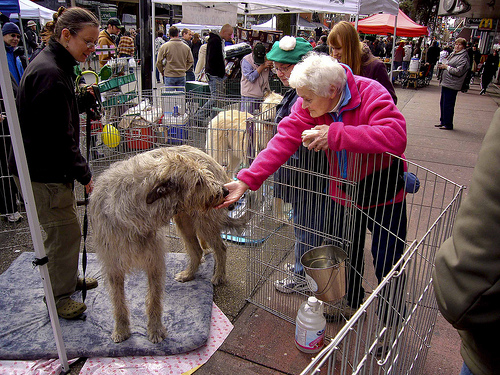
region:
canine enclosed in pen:
[8, 61, 442, 371]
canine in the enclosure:
[82, 138, 252, 337]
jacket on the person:
[17, 45, 97, 174]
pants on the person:
[8, 177, 85, 296]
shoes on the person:
[51, 270, 101, 322]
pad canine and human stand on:
[2, 243, 224, 350]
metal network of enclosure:
[356, 173, 422, 244]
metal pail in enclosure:
[303, 237, 357, 295]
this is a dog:
[92, 144, 214, 335]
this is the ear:
[148, 175, 180, 201]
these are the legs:
[104, 266, 170, 353]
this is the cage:
[353, 165, 443, 260]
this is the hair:
[299, 53, 341, 85]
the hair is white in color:
[297, 57, 342, 84]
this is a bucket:
[297, 246, 351, 289]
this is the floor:
[420, 133, 476, 160]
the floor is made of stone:
[423, 135, 473, 160]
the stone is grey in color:
[416, 133, 466, 159]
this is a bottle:
[292, 289, 329, 352]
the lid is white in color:
[307, 295, 319, 307]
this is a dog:
[92, 137, 237, 344]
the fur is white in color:
[116, 205, 152, 258]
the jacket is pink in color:
[360, 103, 384, 143]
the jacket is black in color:
[36, 69, 56, 114]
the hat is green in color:
[268, 50, 283, 58]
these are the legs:
[108, 247, 164, 347]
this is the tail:
[229, 204, 258, 234]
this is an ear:
[139, 171, 180, 208]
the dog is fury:
[99, 171, 154, 247]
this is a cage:
[377, 165, 442, 252]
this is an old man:
[293, 55, 372, 158]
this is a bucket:
[301, 242, 351, 288]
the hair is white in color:
[295, 57, 333, 87]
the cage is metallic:
[364, 162, 441, 265]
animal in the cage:
[51, 108, 249, 298]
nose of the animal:
[206, 173, 233, 218]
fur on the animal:
[96, 164, 166, 259]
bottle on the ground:
[271, 276, 352, 361]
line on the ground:
[218, 340, 268, 372]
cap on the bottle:
[292, 288, 328, 317]